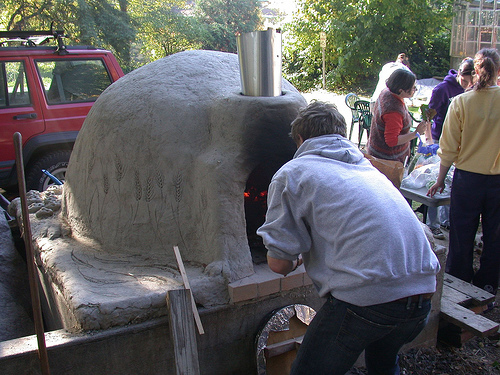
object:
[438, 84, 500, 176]
sweater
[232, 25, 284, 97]
exhaust pipe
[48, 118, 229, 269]
clay oven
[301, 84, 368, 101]
street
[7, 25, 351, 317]
clay oven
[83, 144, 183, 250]
designs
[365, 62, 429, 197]
women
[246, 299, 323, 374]
object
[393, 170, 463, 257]
table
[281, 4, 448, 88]
foliage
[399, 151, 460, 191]
packages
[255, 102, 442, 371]
man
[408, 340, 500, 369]
ground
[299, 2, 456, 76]
tree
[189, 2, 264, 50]
tree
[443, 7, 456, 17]
leaves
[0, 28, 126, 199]
car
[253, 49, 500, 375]
several people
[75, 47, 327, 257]
stone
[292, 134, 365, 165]
hood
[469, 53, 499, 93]
ponytail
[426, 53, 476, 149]
lady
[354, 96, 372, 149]
green chair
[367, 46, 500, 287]
group of women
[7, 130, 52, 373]
wooden stick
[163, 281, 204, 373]
two by four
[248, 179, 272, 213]
coals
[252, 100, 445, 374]
person using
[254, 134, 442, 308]
grey hoodie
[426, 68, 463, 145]
girl's hoodie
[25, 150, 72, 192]
back tire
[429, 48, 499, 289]
woman dressed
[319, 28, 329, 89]
sign in front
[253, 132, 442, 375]
man wearing